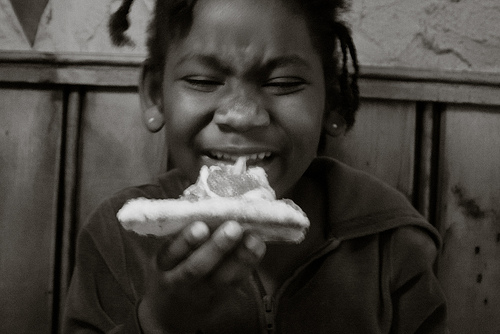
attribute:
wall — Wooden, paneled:
[0, 48, 499, 332]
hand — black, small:
[139, 219, 268, 332]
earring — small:
[144, 115, 155, 131]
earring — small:
[328, 122, 340, 136]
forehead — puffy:
[189, 3, 312, 66]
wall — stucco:
[2, 0, 499, 72]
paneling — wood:
[0, 51, 498, 331]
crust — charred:
[117, 196, 310, 243]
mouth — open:
[197, 141, 281, 172]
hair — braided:
[106, 0, 363, 136]